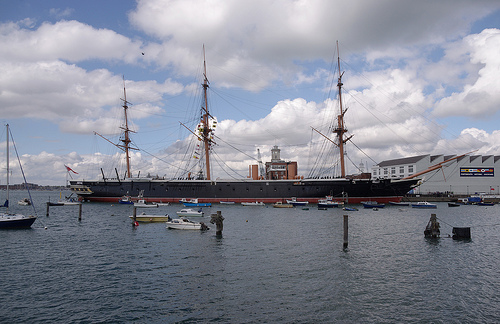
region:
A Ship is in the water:
[53, 27, 453, 232]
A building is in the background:
[368, 140, 498, 220]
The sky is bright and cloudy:
[1, 5, 499, 169]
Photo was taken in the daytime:
[0, 25, 499, 310]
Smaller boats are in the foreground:
[0, 198, 243, 241]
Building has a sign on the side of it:
[456, 162, 498, 183]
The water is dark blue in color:
[41, 212, 473, 315]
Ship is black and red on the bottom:
[50, 128, 446, 215]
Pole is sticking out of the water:
[323, 208, 360, 264]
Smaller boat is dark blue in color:
[3, 204, 51, 239]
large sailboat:
[66, 38, 444, 210]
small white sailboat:
[162, 213, 217, 238]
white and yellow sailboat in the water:
[128, 208, 178, 221]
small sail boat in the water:
[3, 118, 48, 241]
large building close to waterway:
[246, 135, 306, 187]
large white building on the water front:
[370, 158, 499, 206]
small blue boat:
[180, 195, 217, 211]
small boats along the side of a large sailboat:
[286, 193, 351, 212]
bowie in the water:
[413, 208, 493, 272]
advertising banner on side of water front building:
[456, 159, 498, 183]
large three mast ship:
[58, 21, 480, 208]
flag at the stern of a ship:
[59, 153, 95, 184]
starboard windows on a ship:
[216, 182, 309, 193]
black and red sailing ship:
[57, 29, 484, 213]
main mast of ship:
[176, 36, 228, 186]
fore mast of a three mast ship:
[308, 35, 368, 189]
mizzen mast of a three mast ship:
[93, 68, 159, 185]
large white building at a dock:
[376, 150, 498, 208]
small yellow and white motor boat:
[126, 211, 171, 226]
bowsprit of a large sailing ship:
[395, 143, 485, 184]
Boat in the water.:
[34, 60, 448, 246]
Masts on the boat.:
[83, 57, 333, 191]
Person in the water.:
[182, 200, 244, 241]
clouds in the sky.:
[28, 22, 172, 144]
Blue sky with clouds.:
[93, 24, 334, 189]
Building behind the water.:
[377, 145, 431, 188]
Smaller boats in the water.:
[147, 203, 235, 264]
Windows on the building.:
[366, 145, 432, 184]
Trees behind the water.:
[20, 168, 57, 203]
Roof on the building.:
[384, 143, 499, 176]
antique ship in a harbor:
[57, 40, 485, 209]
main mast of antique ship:
[181, 37, 226, 185]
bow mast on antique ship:
[310, 37, 372, 187]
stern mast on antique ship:
[103, 61, 148, 182]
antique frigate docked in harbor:
[55, 28, 482, 210]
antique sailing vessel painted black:
[54, 27, 492, 218]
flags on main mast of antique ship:
[182, 101, 229, 179]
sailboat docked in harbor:
[0, 111, 48, 241]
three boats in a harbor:
[129, 203, 216, 236]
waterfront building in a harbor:
[374, 143, 497, 200]